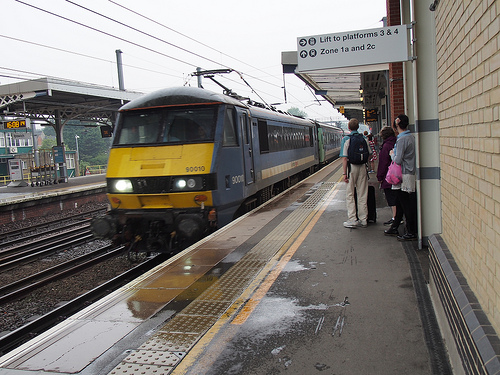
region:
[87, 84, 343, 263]
Grey train on the train platform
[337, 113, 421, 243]
People on the platform waiting for the train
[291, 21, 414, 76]
Direction sign on the post near the wall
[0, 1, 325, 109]
Train lines on top of the train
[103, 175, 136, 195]
Right head light of the train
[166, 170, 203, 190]
Left head light of the train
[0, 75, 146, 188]
Waiting shed on the train platform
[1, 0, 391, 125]
Foggy weather in the sky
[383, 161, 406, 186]
Pink bag carried by a person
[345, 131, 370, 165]
Black bag on the back of the person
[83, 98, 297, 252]
the train is yellowand grey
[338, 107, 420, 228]
the people is standing waiting on train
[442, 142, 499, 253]
the building is brick and tan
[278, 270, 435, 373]
the sidewalk is grey in color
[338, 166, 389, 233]
the man is wearing tan pants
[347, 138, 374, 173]
the man is wearing a backpack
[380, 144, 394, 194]
the lady has on a purple shirt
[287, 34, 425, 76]
there were two signs hanging up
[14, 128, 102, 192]
there was a gas station across the street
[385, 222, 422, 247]
the men shoes is black in color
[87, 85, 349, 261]
train stopped next to a platform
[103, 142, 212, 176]
yellow panel under windshield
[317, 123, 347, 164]
train car behind engine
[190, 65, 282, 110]
pantograph on top of train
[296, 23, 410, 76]
white sign hanging above platform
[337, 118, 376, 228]
person wearing a black backpack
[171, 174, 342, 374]
yellow lines painted on platform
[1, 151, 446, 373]
platform is wet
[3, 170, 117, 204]
platform to the left of the train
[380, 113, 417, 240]
woman holding a pink bag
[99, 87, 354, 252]
Train on the tracks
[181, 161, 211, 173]
Train # 90013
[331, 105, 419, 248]
People waiting for the train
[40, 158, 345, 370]
Puddles on the train platform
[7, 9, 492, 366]
Photo taken during the day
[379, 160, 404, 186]
Pink bag in the woman's hand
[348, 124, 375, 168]
Backpack on the man's back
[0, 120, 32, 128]
16:08 am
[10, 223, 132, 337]
train tracks ade of metal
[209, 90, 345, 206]
The train is primarily gray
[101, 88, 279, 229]
gray and yellow light rail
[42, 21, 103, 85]
white clouds in blue sky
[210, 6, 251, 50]
white clouds in blue sky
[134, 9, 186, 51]
white clouds in blue sky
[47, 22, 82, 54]
white clouds in blue sky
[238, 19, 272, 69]
white clouds in blue sky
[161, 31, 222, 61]
white clouds in blue sky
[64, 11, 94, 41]
white clouds in blue sky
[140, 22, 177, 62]
white clouds in blue sky